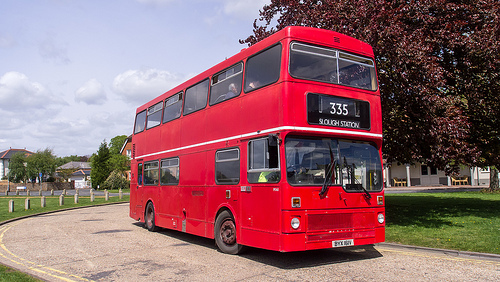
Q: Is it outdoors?
A: Yes, it is outdoors.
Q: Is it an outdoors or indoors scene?
A: It is outdoors.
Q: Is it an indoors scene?
A: No, it is outdoors.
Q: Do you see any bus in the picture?
A: Yes, there is a bus.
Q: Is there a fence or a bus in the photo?
A: Yes, there is a bus.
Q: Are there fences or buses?
A: Yes, there is a bus.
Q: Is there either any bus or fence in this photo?
A: Yes, there is a bus.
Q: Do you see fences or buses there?
A: Yes, there is a bus.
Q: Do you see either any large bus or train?
A: Yes, there is a large bus.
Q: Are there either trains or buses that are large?
A: Yes, the bus is large.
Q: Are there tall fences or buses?
A: Yes, there is a tall bus.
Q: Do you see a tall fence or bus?
A: Yes, there is a tall bus.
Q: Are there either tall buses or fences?
A: Yes, there is a tall bus.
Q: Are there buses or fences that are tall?
A: Yes, the bus is tall.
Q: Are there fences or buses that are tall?
A: Yes, the bus is tall.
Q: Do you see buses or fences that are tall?
A: Yes, the bus is tall.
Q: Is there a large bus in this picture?
A: Yes, there is a large bus.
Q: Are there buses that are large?
A: Yes, there is a bus that is large.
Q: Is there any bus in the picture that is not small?
A: Yes, there is a large bus.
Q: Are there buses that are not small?
A: Yes, there is a large bus.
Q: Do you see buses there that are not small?
A: Yes, there is a large bus.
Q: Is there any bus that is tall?
A: Yes, there is a tall bus.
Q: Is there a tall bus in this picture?
A: Yes, there is a tall bus.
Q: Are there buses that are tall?
A: Yes, there is a bus that is tall.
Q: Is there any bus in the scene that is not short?
A: Yes, there is a tall bus.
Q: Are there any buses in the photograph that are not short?
A: Yes, there is a tall bus.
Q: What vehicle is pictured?
A: The vehicle is a bus.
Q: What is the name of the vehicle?
A: The vehicle is a bus.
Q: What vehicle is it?
A: The vehicle is a bus.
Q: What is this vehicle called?
A: This is a bus.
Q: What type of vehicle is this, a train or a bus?
A: This is a bus.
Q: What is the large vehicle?
A: The vehicle is a bus.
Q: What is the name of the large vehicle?
A: The vehicle is a bus.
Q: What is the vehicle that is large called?
A: The vehicle is a bus.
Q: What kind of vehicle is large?
A: The vehicle is a bus.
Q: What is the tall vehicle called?
A: The vehicle is a bus.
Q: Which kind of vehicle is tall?
A: The vehicle is a bus.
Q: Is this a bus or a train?
A: This is a bus.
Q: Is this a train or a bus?
A: This is a bus.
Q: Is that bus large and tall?
A: Yes, the bus is large and tall.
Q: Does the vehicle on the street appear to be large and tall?
A: Yes, the bus is large and tall.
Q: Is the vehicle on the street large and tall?
A: Yes, the bus is large and tall.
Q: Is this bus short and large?
A: No, the bus is large but tall.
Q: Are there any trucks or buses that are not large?
A: No, there is a bus but it is large.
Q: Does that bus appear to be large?
A: Yes, the bus is large.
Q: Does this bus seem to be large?
A: Yes, the bus is large.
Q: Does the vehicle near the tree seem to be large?
A: Yes, the bus is large.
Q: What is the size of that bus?
A: The bus is large.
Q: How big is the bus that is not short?
A: The bus is large.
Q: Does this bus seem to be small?
A: No, the bus is large.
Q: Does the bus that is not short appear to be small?
A: No, the bus is large.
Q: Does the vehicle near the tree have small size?
A: No, the bus is large.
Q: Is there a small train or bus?
A: No, there is a bus but it is large.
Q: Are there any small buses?
A: No, there is a bus but it is large.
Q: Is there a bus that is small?
A: No, there is a bus but it is large.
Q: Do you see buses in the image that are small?
A: No, there is a bus but it is large.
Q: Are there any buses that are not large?
A: No, there is a bus but it is large.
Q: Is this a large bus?
A: Yes, this is a large bus.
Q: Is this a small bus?
A: No, this is a large bus.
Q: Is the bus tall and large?
A: Yes, the bus is tall and large.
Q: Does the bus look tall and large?
A: Yes, the bus is tall and large.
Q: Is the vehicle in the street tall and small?
A: No, the bus is tall but large.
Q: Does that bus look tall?
A: Yes, the bus is tall.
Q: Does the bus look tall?
A: Yes, the bus is tall.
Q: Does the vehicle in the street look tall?
A: Yes, the bus is tall.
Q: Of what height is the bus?
A: The bus is tall.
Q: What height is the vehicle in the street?
A: The bus is tall.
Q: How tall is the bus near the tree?
A: The bus is tall.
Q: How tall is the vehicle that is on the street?
A: The bus is tall.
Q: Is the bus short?
A: No, the bus is tall.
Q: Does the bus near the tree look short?
A: No, the bus is tall.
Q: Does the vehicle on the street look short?
A: No, the bus is tall.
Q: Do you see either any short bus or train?
A: No, there is a bus but it is tall.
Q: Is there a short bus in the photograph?
A: No, there is a bus but it is tall.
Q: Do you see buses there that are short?
A: No, there is a bus but it is tall.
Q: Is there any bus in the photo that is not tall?
A: No, there is a bus but it is tall.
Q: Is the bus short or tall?
A: The bus is tall.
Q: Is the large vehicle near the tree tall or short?
A: The bus is tall.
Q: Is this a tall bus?
A: Yes, this is a tall bus.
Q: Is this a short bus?
A: No, this is a tall bus.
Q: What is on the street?
A: The bus is on the street.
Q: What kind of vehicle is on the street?
A: The vehicle is a bus.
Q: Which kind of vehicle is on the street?
A: The vehicle is a bus.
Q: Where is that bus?
A: The bus is on the street.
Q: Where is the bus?
A: The bus is on the street.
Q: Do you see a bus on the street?
A: Yes, there is a bus on the street.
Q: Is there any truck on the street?
A: No, there is a bus on the street.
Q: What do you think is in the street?
A: The bus is in the street.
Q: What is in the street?
A: The bus is in the street.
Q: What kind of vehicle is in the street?
A: The vehicle is a bus.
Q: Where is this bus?
A: The bus is in the street.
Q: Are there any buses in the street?
A: Yes, there is a bus in the street.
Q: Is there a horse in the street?
A: No, there is a bus in the street.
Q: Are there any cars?
A: No, there are no cars.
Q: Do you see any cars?
A: No, there are no cars.